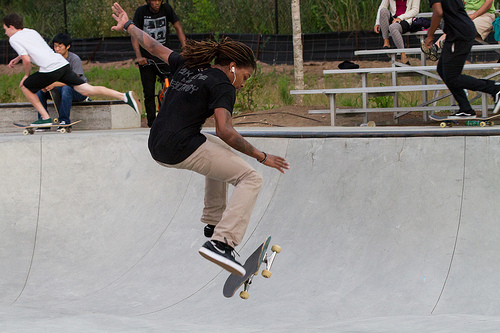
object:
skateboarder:
[102, 1, 297, 282]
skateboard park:
[7, 33, 495, 333]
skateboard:
[220, 235, 280, 300]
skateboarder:
[417, 0, 500, 117]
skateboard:
[426, 111, 498, 128]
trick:
[99, 1, 312, 310]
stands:
[289, 5, 491, 125]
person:
[0, 14, 142, 126]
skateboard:
[11, 119, 84, 135]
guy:
[127, 0, 188, 127]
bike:
[135, 56, 174, 111]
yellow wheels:
[239, 289, 251, 300]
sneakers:
[199, 238, 247, 277]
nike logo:
[209, 240, 226, 255]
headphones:
[229, 63, 239, 84]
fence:
[0, 27, 500, 63]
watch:
[119, 18, 136, 33]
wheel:
[261, 269, 272, 279]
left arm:
[126, 21, 185, 65]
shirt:
[145, 49, 239, 166]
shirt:
[8, 27, 70, 77]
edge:
[0, 123, 500, 140]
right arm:
[211, 84, 262, 159]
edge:
[280, 88, 363, 95]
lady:
[370, 0, 423, 71]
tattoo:
[230, 134, 255, 156]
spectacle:
[3, 1, 496, 160]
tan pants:
[153, 136, 266, 256]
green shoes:
[120, 89, 141, 116]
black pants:
[435, 35, 498, 117]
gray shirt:
[433, 0, 478, 44]